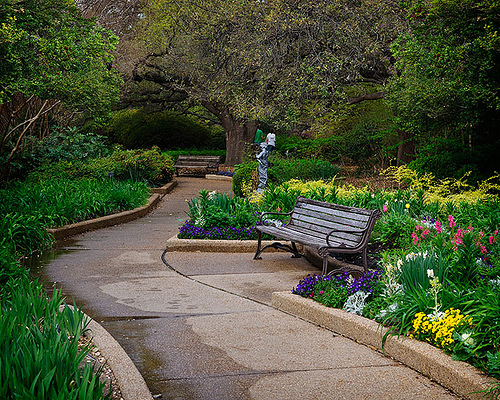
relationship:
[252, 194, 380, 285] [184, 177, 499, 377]
bench amidst flowers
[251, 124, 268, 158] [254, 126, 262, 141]
people wearing green shirt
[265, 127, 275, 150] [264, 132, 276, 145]
person wearing shirt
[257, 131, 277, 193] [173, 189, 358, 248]
statue amidst flowers